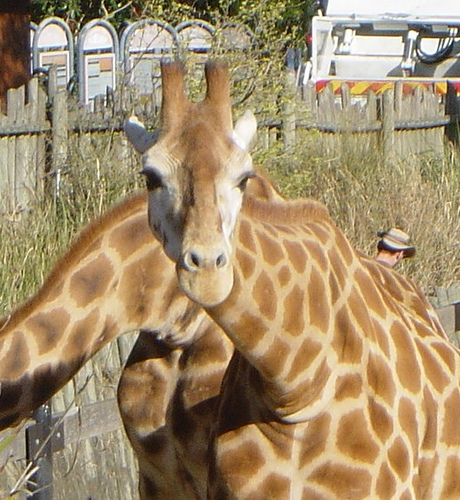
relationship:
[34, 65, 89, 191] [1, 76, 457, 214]
wooden posts holding fence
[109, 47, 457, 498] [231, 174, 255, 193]
giraffe has eye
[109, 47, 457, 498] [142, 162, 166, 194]
giraffe has eye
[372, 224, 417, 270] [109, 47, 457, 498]
man behind giraffe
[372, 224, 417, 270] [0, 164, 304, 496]
man behind giraffe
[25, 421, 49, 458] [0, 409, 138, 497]
hinge on door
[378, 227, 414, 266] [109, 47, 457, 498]
head behind giraffe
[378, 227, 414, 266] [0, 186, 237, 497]
head behind giraffe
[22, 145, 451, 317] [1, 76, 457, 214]
weeds between fence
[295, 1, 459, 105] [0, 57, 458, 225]
truck behind fence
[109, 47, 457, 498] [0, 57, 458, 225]
giraffe by fence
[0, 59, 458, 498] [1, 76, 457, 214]
giraffe by fence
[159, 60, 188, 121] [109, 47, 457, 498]
horn on giraffe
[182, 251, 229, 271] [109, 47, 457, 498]
nostrils on giraffe